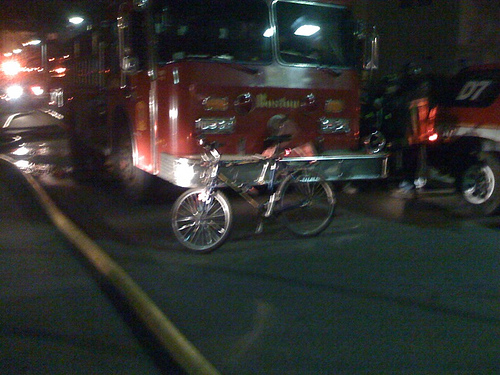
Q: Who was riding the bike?
A: A young boy.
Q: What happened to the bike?
A: It was hit.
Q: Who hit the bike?
A: The truck.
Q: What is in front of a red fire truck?
A: Lights.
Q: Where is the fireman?
A: By the fire truck.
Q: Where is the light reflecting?
A: By silver bike.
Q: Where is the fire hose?
A: On the ground.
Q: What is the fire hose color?
A: Yellow.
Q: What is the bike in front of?
A: Fire engine.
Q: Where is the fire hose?
A: On floor.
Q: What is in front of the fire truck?
A: Windshield.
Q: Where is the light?
A: Behind fire truck.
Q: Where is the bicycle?
A: In front of bus.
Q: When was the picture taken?
A: Night.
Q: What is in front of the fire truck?
A: Bicycle.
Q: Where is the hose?
A: Next to the curb.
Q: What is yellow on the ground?
A: The hose.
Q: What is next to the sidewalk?
A: A hose.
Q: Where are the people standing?
A: Next to the firetruck.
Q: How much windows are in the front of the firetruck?
A: Two.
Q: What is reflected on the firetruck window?
A: A light.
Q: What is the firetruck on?
A: A cement floor.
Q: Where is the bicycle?
A: In front of the firetruck.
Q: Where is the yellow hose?
A: Right of the firetruck.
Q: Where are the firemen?
A: Left of the firetruck.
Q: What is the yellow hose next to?
A: A sidewalk.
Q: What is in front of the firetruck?
A: A bicycle.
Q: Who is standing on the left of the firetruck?
A: The firemen.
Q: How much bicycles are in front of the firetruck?
A: One.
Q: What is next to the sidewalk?
A: A yellow hose.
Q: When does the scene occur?
A: Night time.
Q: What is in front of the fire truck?
A: A bicycle.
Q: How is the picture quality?
A: Very blurry.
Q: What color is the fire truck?
A: Red.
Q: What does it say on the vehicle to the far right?
A: D7.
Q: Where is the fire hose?
A: Lying in the street.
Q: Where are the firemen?
A: To the right of the truck.